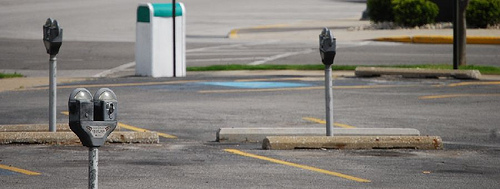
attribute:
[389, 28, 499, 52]
paint — yellow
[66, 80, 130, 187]
meter — silver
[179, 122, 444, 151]
curbs — concrete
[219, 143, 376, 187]
stripe — yellow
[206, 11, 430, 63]
side walk — concrete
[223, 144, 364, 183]
line — yellow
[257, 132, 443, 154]
barrier — concrete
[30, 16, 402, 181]
meters — grey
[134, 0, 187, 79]
trash can — green, white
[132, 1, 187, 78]
can — metal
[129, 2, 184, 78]
mailbox — white, blue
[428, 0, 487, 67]
tree — barren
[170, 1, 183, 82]
pole — black